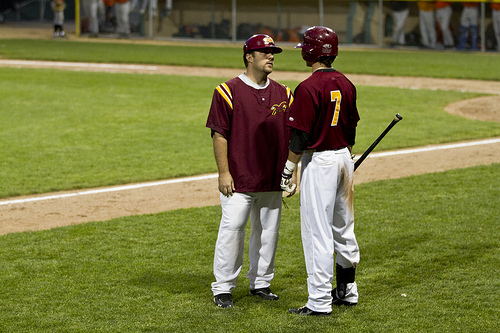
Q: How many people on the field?
A: Two.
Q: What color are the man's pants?
A: White.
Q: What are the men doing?
A: Looking at each other.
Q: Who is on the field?
A: Men.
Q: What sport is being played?
A: Baseball.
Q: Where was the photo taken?
A: At the baseball field.